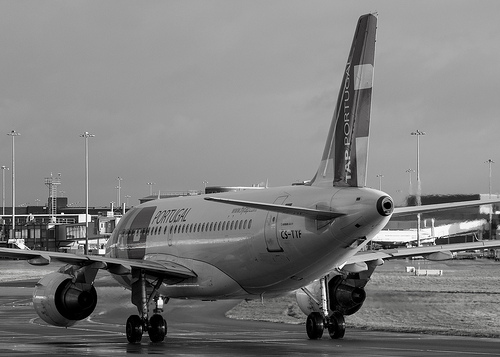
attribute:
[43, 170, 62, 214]
tower — air traffic control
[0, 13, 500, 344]
airplane — large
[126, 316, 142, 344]
wheel — black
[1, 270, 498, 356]
tarmac — runway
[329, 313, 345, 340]
wheel — black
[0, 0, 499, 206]
sky — grey, cloudy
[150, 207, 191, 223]
word — portugal